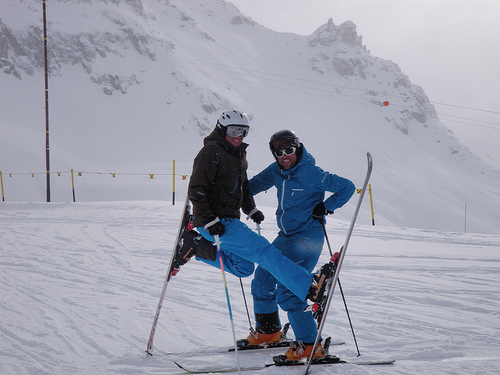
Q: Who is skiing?
A: A man and woman.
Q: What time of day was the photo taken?
A: Daytime.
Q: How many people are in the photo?
A: Two.